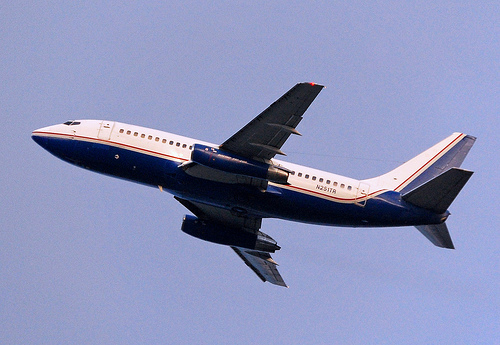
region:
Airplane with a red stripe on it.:
[28, 79, 478, 292]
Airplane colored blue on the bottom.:
[30, 80, 478, 290]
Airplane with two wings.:
[30, 77, 481, 290]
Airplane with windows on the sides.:
[28, 78, 478, 293]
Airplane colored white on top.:
[28, 81, 476, 292]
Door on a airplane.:
[94, 117, 116, 147]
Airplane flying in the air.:
[28, 79, 480, 291]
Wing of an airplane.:
[180, 81, 325, 190]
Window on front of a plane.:
[60, 115, 82, 130]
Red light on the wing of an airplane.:
[302, 79, 321, 88]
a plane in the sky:
[16, 50, 498, 298]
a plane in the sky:
[5, 33, 496, 298]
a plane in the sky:
[5, 35, 482, 327]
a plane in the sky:
[20, 32, 485, 324]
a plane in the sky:
[16, 47, 484, 327]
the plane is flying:
[22, 52, 482, 320]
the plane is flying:
[10, 61, 487, 295]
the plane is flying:
[2, 36, 497, 328]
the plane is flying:
[15, 65, 479, 321]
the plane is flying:
[22, 42, 484, 322]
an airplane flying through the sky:
[31, 53, 470, 283]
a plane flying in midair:
[31, 69, 466, 301]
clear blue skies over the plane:
[31, 198, 160, 315]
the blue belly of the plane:
[136, 169, 271, 218]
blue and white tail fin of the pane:
[373, 129, 476, 224]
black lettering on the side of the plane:
[316, 186, 339, 199]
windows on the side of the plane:
[118, 124, 193, 152]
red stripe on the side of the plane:
[89, 133, 179, 166]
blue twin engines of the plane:
[169, 128, 282, 270]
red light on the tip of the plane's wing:
[301, 76, 323, 90]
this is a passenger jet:
[28, 56, 490, 293]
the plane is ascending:
[22, 73, 487, 319]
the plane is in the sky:
[23, 53, 493, 289]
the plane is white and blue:
[20, 50, 499, 334]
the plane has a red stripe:
[10, 96, 495, 222]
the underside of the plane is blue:
[14, 75, 498, 315]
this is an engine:
[166, 130, 308, 205]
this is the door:
[95, 108, 126, 159]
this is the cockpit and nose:
[27, 94, 79, 172]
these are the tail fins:
[401, 60, 483, 301]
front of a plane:
[23, 102, 106, 173]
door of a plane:
[96, 114, 118, 144]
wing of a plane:
[228, 222, 301, 294]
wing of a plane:
[228, 64, 345, 159]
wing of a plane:
[413, 150, 477, 207]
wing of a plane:
[395, 105, 485, 185]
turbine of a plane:
[177, 207, 239, 241]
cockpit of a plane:
[36, 114, 88, 152]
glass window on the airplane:
[175, 137, 180, 147]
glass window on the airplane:
[167, 136, 172, 147]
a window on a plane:
[118, 122, 125, 135]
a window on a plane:
[61, 117, 70, 127]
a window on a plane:
[74, 118, 79, 125]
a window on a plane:
[133, 130, 138, 137]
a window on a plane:
[137, 128, 146, 140]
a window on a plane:
[147, 134, 152, 140]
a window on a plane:
[155, 135, 157, 145]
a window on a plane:
[183, 142, 189, 149]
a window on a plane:
[291, 166, 300, 178]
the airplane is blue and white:
[58, 73, 380, 253]